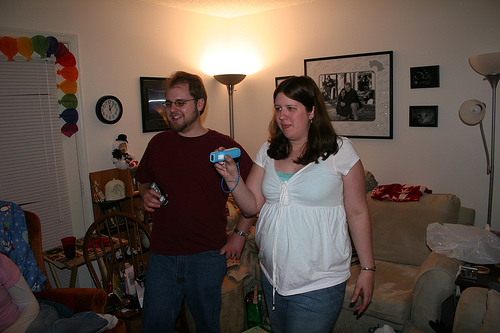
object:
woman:
[210, 76, 378, 333]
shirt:
[253, 135, 361, 310]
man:
[132, 71, 257, 332]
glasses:
[160, 97, 197, 108]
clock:
[95, 95, 123, 125]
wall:
[73, 12, 241, 108]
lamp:
[213, 74, 246, 139]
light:
[195, 47, 264, 77]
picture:
[303, 50, 394, 139]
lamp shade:
[468, 51, 499, 76]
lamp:
[468, 52, 499, 226]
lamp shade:
[458, 98, 486, 126]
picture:
[410, 65, 441, 90]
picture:
[408, 105, 438, 127]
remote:
[210, 147, 243, 163]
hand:
[213, 146, 238, 181]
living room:
[0, 0, 499, 332]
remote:
[150, 182, 170, 205]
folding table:
[43, 232, 129, 288]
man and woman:
[132, 71, 377, 333]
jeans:
[140, 249, 228, 333]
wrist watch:
[360, 265, 376, 270]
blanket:
[370, 183, 432, 202]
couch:
[330, 169, 476, 332]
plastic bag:
[426, 221, 499, 265]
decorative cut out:
[0, 35, 80, 138]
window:
[0, 38, 82, 288]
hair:
[163, 71, 208, 116]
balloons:
[60, 121, 79, 138]